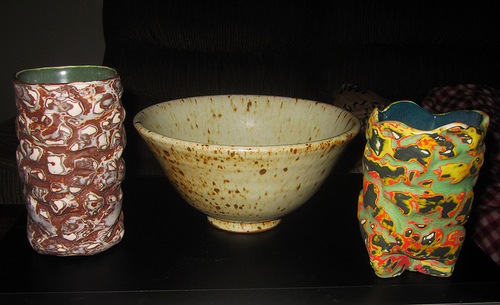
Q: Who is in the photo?
A: Nobody.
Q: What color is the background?
A: Black.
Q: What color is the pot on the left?
A: Burnt sienna.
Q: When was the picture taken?
A: Daytime.